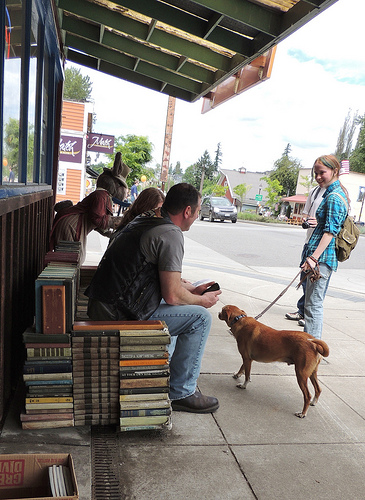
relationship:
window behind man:
[0, 1, 63, 183] [88, 177, 220, 406]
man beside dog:
[88, 177, 220, 406] [222, 299, 326, 413]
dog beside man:
[222, 299, 326, 413] [88, 177, 220, 406]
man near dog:
[88, 177, 220, 406] [222, 299, 326, 413]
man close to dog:
[88, 177, 220, 406] [222, 299, 326, 413]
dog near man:
[222, 299, 326, 413] [88, 177, 220, 406]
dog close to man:
[222, 299, 326, 413] [88, 177, 220, 406]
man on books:
[88, 177, 220, 406] [33, 240, 167, 452]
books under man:
[33, 240, 167, 452] [88, 177, 220, 406]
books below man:
[33, 240, 167, 452] [88, 177, 220, 406]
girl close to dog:
[289, 149, 352, 350] [222, 299, 326, 413]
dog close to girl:
[222, 299, 326, 413] [289, 149, 352, 350]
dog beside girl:
[222, 299, 326, 413] [289, 149, 352, 350]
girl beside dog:
[289, 149, 352, 350] [222, 299, 326, 413]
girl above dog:
[289, 149, 352, 350] [222, 299, 326, 413]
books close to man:
[33, 240, 167, 452] [88, 177, 220, 406]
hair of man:
[167, 175, 197, 204] [88, 177, 220, 406]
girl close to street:
[289, 149, 352, 350] [184, 210, 355, 270]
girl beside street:
[289, 149, 352, 350] [184, 210, 355, 270]